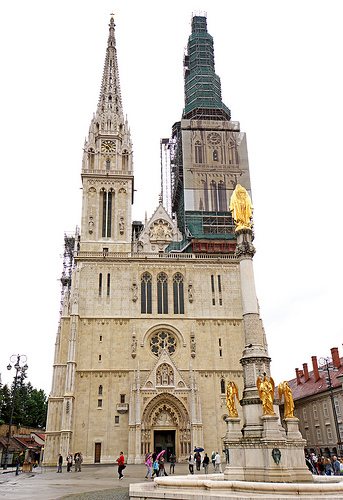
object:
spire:
[81, 12, 133, 174]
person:
[78, 452, 82, 471]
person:
[66, 453, 73, 473]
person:
[73, 451, 81, 471]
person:
[145, 456, 154, 479]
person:
[152, 459, 159, 476]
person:
[159, 457, 164, 476]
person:
[189, 452, 194, 474]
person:
[203, 453, 209, 473]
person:
[212, 451, 222, 473]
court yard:
[0, 463, 227, 499]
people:
[56, 454, 62, 474]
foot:
[119, 476, 123, 480]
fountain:
[128, 372, 343, 500]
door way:
[141, 394, 191, 465]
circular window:
[147, 328, 179, 359]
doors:
[154, 430, 176, 463]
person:
[168, 454, 175, 475]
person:
[211, 451, 216, 467]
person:
[194, 452, 201, 471]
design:
[140, 393, 191, 428]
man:
[116, 451, 126, 481]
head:
[120, 451, 124, 455]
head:
[271, 448, 281, 464]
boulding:
[41, 12, 270, 467]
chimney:
[311, 356, 320, 383]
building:
[274, 346, 343, 461]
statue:
[228, 183, 253, 233]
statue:
[225, 378, 239, 417]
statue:
[257, 374, 278, 416]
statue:
[278, 381, 297, 418]